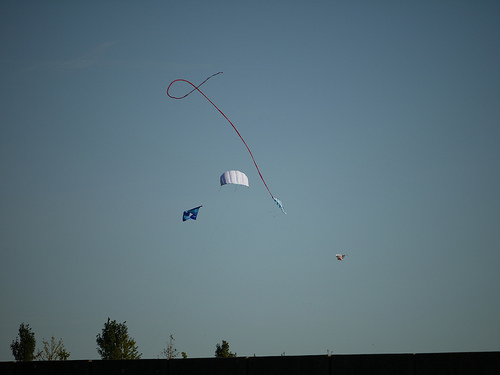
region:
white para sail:
[207, 162, 257, 200]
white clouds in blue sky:
[19, 14, 111, 80]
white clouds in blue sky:
[27, 90, 105, 150]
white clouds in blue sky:
[42, 151, 114, 229]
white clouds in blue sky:
[45, 222, 136, 269]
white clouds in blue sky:
[156, 251, 246, 285]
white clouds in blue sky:
[273, 238, 314, 301]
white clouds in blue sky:
[315, 27, 494, 135]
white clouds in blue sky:
[327, 131, 443, 206]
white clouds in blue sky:
[400, 196, 446, 300]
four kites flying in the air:
[141, 62, 363, 277]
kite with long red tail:
[150, 60, 304, 224]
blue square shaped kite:
[178, 201, 200, 223]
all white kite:
[215, 167, 252, 197]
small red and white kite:
[325, 245, 353, 265]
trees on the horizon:
[6, 315, 248, 360]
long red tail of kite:
[160, 67, 278, 187]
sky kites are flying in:
[17, 24, 495, 351]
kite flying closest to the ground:
[324, 245, 348, 268]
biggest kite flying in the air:
[214, 172, 248, 191]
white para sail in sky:
[219, 154, 283, 228]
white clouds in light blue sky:
[20, 12, 92, 73]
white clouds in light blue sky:
[37, 85, 108, 157]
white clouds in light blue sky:
[4, 136, 106, 218]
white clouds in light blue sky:
[24, 214, 142, 288]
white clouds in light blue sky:
[129, 242, 214, 314]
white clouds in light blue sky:
[251, 239, 349, 291]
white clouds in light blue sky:
[374, 164, 461, 274]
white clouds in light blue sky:
[247, 6, 379, 97]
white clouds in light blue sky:
[353, 45, 454, 192]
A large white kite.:
[211, 163, 253, 193]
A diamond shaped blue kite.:
[166, 199, 205, 226]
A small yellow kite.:
[332, 253, 349, 263]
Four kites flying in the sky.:
[137, 42, 379, 298]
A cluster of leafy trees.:
[5, 313, 265, 373]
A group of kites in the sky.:
[145, 58, 364, 298]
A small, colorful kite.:
[323, 244, 363, 275]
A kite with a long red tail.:
[250, 148, 305, 225]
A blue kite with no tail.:
[175, 185, 210, 242]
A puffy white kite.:
[199, 154, 253, 199]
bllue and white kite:
[197, 156, 270, 220]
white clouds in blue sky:
[14, 22, 70, 84]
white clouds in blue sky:
[12, 129, 107, 234]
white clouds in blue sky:
[64, 240, 212, 325]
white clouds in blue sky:
[219, 252, 280, 286]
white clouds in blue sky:
[236, 220, 289, 318]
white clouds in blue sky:
[111, 20, 189, 68]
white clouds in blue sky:
[287, 30, 425, 126]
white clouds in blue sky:
[342, 116, 472, 274]